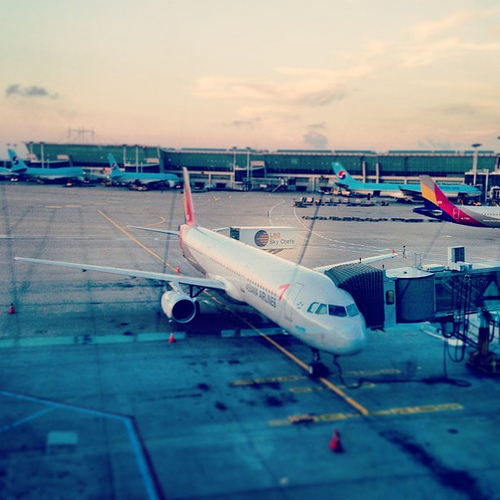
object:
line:
[96, 208, 179, 273]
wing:
[4, 255, 229, 293]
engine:
[154, 275, 199, 326]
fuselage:
[172, 220, 368, 355]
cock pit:
[299, 294, 372, 334]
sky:
[0, 2, 499, 152]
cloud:
[0, 82, 61, 100]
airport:
[0, 135, 500, 500]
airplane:
[13, 165, 400, 381]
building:
[0, 142, 500, 182]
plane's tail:
[328, 162, 360, 184]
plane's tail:
[415, 170, 457, 218]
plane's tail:
[178, 165, 196, 226]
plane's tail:
[103, 153, 119, 173]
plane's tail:
[6, 147, 26, 167]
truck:
[215, 223, 297, 252]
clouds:
[197, 66, 351, 106]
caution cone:
[327, 424, 347, 456]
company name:
[249, 280, 277, 313]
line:
[61, 326, 286, 347]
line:
[134, 209, 170, 229]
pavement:
[0, 185, 500, 500]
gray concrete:
[28, 206, 93, 254]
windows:
[304, 299, 326, 315]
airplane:
[325, 156, 485, 213]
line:
[273, 400, 465, 427]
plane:
[409, 165, 498, 228]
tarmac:
[0, 182, 500, 498]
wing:
[176, 167, 198, 233]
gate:
[320, 252, 498, 380]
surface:
[0, 181, 499, 500]